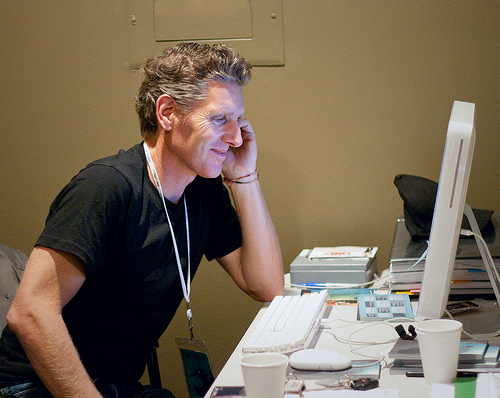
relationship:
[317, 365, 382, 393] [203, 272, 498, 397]
key set on top of desk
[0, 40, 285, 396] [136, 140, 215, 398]
man wearing tag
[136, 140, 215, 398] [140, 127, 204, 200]
tag around neck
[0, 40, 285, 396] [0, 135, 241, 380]
man wearing shirt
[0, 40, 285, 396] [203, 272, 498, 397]
man sitting at desk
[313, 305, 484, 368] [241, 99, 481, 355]
cords attached to computer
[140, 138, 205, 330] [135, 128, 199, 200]
lanyard hanging around neck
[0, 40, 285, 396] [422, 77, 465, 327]
man staring at monitor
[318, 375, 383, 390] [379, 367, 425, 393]
keys on top of desk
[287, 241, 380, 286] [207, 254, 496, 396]
box on top of desk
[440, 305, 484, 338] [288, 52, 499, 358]
cable plugged into computer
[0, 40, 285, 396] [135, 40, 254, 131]
man with hair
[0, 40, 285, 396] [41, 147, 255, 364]
man wearing shirt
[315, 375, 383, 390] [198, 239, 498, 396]
keys on desk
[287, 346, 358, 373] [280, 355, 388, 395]
mouse on pad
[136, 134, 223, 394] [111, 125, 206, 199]
tag around neck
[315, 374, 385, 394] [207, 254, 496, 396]
keys on desk